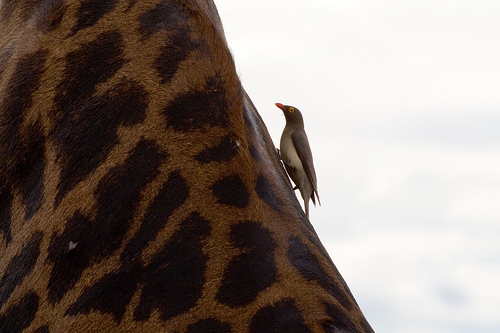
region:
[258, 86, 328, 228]
small bird on giraffe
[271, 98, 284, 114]
orange beak on bird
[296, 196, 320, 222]
tail feather of bird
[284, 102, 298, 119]
yellow eye of bird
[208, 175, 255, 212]
black spot of animal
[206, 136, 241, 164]
black spot of animal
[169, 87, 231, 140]
black spot of animal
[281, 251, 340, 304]
black spot of animal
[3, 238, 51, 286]
black spot of animal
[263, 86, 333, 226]
a bird on a giraffe back.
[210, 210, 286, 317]
a spot on a giraffe.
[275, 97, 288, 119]
a beak on a small bird.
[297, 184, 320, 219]
a tail feather.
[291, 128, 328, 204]
a wing on a bird.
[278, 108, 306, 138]
the head of a bird.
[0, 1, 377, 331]
a giraffe with a bird on it's back.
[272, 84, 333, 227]
a small bird.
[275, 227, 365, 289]
a spot on a giraffe.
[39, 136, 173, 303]
a long spot on a giraffe.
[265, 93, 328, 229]
this is an 'oxpecker', i kid thee not, aka the perhaps even more glorious 'african tick bird'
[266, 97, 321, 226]
it's cute, i know, but it's a parasite. red beak, yellow eye & all.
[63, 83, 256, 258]
@ present it's probably looking for some dandruff to munch. i see a few flakes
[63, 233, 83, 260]
this, otoh, might be a fly. it'll probably eat that too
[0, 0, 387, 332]
this, otoh, as has been noted by everyone looking at this photo, is a giraffe's neck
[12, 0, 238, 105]
it has spots on it, i know, & so does everyone else who doesnt think they're stripes. or it's a zebra.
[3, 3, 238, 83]
the fur on the hide, if you look close, is kind of fluffed+tussled, looks a little messy. this is probably cos of the oxpecker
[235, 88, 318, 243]
the area beneath the oxpecker seems a bit balding? that's the oxpecker too, looking for sores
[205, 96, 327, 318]
heart shaped spot, sort of tilted, beneath pretty grey wing, brown head bird. but it eats earwax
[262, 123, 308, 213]
too low on the neck to get to the ears now, though. & it's just standing there-i can see 1 leg-& it's soft grey underbelly has no blood on it, so it's giraffe's been having a decent day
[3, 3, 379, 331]
A giraffe and a bird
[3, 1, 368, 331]
A giraffe neck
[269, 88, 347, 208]
A bird on the giraffe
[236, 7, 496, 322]
clouds in the sky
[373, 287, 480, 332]
A blue sky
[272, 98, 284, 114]
orange beak on the bird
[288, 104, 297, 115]
yellow eyes on the bird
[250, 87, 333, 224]
a bird resting on a giraffe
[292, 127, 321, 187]
The left wing of the bird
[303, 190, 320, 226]
the tail feathers of the bird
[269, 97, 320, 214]
brown bird pirched on giraffe neck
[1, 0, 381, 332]
neck of giraffe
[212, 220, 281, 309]
brown spot on giraffe neck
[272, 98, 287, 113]
beak of bird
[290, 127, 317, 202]
left wing of bird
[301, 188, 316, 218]
back tail feather of bird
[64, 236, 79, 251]
white blotch on a giraffe spot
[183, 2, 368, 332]
spine of giraffe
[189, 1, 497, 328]
white sky in the background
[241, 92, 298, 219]
reflection area of giraffe's neck